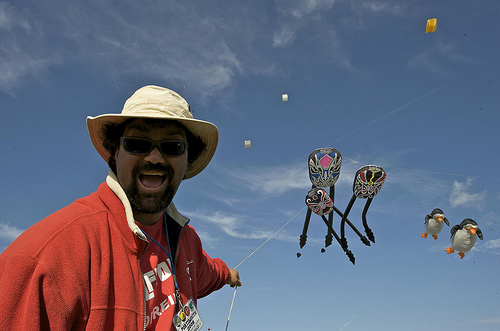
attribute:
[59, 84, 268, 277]
man — smiling, wearing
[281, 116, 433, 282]
kites — up, penguin, flying, yellow, mask, themed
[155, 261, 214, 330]
tag — id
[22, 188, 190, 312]
sweatshirt — red, fleece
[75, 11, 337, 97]
skies — clear, large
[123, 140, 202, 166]
sunglasses — worn, black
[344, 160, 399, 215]
kite — here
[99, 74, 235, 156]
hat — tan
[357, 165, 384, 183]
mask — red, kabuki